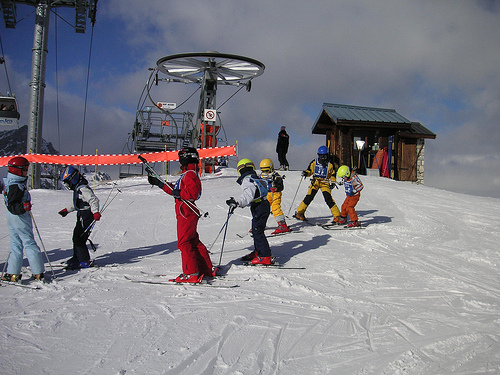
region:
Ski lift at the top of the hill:
[129, 45, 262, 150]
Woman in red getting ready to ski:
[158, 146, 218, 286]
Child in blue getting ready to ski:
[1, 156, 58, 297]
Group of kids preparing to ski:
[301, 143, 368, 230]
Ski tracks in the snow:
[201, 310, 491, 373]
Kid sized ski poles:
[210, 202, 233, 278]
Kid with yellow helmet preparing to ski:
[256, 152, 295, 237]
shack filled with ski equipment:
[357, 103, 434, 182]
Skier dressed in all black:
[272, 123, 299, 168]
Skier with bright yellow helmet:
[223, 153, 268, 269]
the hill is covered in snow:
[261, 272, 456, 370]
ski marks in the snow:
[155, 308, 468, 372]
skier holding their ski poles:
[140, 142, 208, 245]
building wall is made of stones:
[417, 143, 454, 198]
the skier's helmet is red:
[3, 159, 33, 185]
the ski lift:
[135, 12, 287, 177]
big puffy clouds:
[265, 6, 499, 90]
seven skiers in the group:
[11, 147, 380, 317]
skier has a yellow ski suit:
[260, 177, 292, 218]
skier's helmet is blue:
[323, 145, 336, 162]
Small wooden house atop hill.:
[313, 99, 437, 181]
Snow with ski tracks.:
[279, 279, 498, 369]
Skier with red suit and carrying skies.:
[132, 149, 227, 286]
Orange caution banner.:
[12, 144, 252, 165]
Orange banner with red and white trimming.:
[32, 142, 238, 166]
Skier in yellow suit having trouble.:
[285, 144, 345, 224]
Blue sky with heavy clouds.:
[305, 20, 472, 105]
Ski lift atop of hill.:
[119, 49, 271, 176]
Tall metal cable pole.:
[27, 6, 51, 192]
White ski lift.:
[0, 96, 20, 136]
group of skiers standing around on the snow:
[0, 144, 377, 302]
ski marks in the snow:
[161, 310, 245, 374]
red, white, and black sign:
[203, 106, 218, 123]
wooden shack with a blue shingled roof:
[305, 90, 438, 180]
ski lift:
[113, 36, 259, 176]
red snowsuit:
[151, 159, 222, 284]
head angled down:
[53, 157, 83, 191]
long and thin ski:
[127, 272, 239, 299]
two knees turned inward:
[338, 198, 357, 218]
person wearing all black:
[271, 121, 293, 169]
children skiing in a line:
[5, 150, 376, 303]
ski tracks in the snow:
[157, 312, 308, 373]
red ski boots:
[167, 245, 324, 307]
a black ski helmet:
[150, 127, 209, 174]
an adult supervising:
[256, 113, 311, 170]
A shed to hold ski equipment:
[301, 99, 450, 184]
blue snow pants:
[0, 215, 65, 286]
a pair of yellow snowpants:
[265, 186, 297, 223]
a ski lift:
[115, 32, 297, 193]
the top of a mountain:
[1, 111, 99, 202]